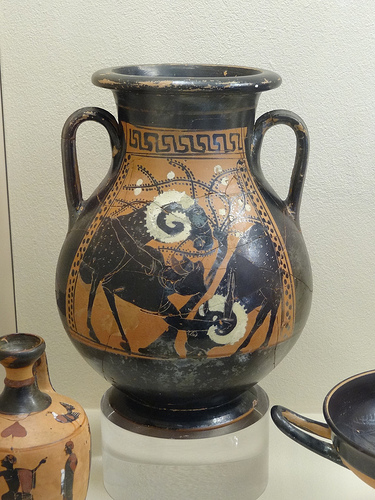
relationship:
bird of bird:
[43, 400, 82, 429] [43, 395, 82, 425]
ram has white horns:
[193, 214, 292, 354] [196, 292, 252, 349]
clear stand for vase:
[101, 406, 268, 499] [53, 65, 314, 431]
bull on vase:
[91, 215, 215, 358] [56, 89, 274, 340]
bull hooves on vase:
[81, 324, 138, 359] [53, 65, 314, 431]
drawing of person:
[51, 437, 87, 498] [57, 442, 80, 498]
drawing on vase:
[146, 187, 217, 250] [53, 65, 314, 431]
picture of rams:
[86, 139, 290, 362] [85, 191, 282, 360]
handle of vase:
[53, 101, 165, 177] [53, 65, 314, 431]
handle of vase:
[247, 108, 311, 223] [53, 65, 314, 431]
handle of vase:
[269, 403, 340, 464] [266, 369, 373, 498]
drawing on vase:
[0, 457, 51, 499] [2, 334, 87, 493]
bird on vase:
[43, 400, 82, 429] [2, 334, 87, 493]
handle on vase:
[249, 103, 311, 205] [53, 65, 314, 431]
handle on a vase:
[272, 403, 340, 465] [270, 376, 373, 495]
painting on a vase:
[60, 432, 85, 498] [2, 334, 87, 493]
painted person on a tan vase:
[3, 448, 46, 498] [0, 333, 92, 497]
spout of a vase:
[1, 330, 51, 413] [2, 334, 87, 493]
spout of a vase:
[88, 64, 294, 145] [42, 55, 329, 404]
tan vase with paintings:
[0, 333, 92, 497] [6, 395, 83, 498]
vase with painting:
[53, 65, 314, 431] [188, 225, 277, 357]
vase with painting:
[53, 65, 314, 431] [78, 189, 213, 345]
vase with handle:
[273, 363, 372, 499] [269, 403, 340, 464]